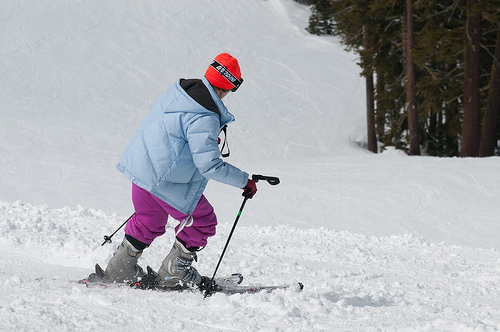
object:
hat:
[204, 52, 242, 90]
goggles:
[231, 77, 244, 92]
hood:
[160, 77, 219, 114]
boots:
[102, 236, 213, 291]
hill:
[4, 206, 500, 332]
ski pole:
[200, 174, 282, 299]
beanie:
[205, 52, 241, 89]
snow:
[339, 194, 376, 229]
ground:
[318, 230, 390, 265]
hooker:
[101, 212, 136, 245]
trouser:
[122, 177, 217, 251]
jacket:
[115, 76, 250, 218]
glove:
[240, 178, 258, 199]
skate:
[206, 281, 303, 299]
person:
[35, 52, 305, 294]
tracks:
[34, 301, 145, 329]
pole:
[202, 174, 279, 298]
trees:
[297, 0, 500, 158]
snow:
[0, 5, 499, 331]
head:
[204, 52, 244, 92]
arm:
[186, 115, 249, 189]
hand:
[241, 178, 258, 199]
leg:
[102, 182, 167, 283]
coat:
[113, 77, 249, 215]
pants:
[123, 181, 218, 247]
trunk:
[357, 66, 390, 148]